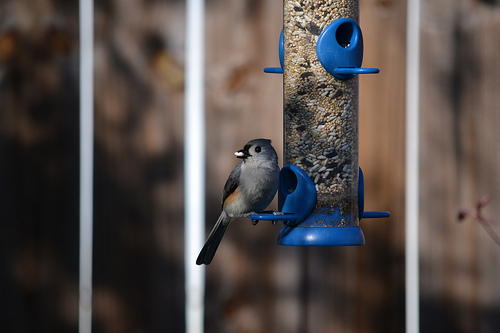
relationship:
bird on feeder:
[196, 138, 283, 265] [252, 0, 394, 246]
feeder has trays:
[252, 0, 394, 246] [247, 15, 392, 228]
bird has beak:
[196, 138, 283, 265] [234, 145, 250, 159]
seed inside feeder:
[284, 0, 359, 222] [252, 0, 394, 246]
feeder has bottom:
[252, 0, 394, 246] [275, 227, 368, 247]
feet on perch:
[247, 209, 286, 226] [249, 212, 297, 222]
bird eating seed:
[196, 138, 283, 265] [284, 0, 359, 222]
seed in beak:
[234, 152, 246, 156] [234, 145, 250, 159]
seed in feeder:
[284, 0, 359, 222] [252, 0, 394, 246]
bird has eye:
[196, 138, 283, 265] [253, 145, 262, 154]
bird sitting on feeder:
[196, 138, 283, 265] [252, 0, 394, 246]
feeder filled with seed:
[252, 0, 394, 246] [284, 0, 359, 222]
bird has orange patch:
[196, 138, 283, 265] [224, 184, 244, 204]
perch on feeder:
[249, 212, 297, 222] [252, 0, 394, 246]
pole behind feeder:
[79, 1, 93, 331] [252, 0, 394, 246]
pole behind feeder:
[186, 0, 204, 331] [252, 0, 394, 246]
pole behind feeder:
[406, 0, 421, 331] [252, 0, 394, 246]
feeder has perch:
[252, 0, 394, 246] [249, 212, 297, 222]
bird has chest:
[196, 138, 283, 265] [241, 167, 282, 204]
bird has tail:
[196, 138, 283, 265] [196, 212, 226, 267]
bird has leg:
[196, 138, 283, 265] [227, 212, 263, 224]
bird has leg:
[196, 138, 283, 265] [259, 209, 284, 223]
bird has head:
[196, 138, 283, 265] [232, 136, 280, 162]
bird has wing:
[196, 138, 283, 265] [222, 163, 243, 200]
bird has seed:
[196, 138, 283, 265] [234, 152, 246, 156]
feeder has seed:
[252, 0, 394, 246] [284, 0, 359, 222]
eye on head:
[253, 145, 262, 154] [232, 136, 280, 162]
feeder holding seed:
[252, 0, 394, 246] [284, 0, 359, 222]